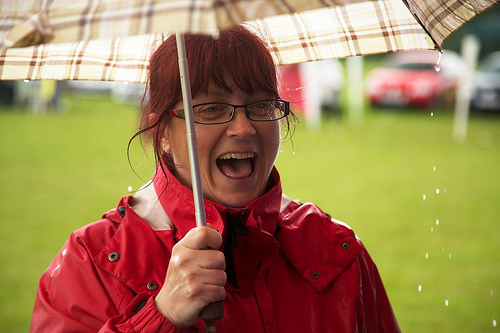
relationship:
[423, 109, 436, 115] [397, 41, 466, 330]
drop of rain water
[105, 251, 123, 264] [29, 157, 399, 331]
button on coat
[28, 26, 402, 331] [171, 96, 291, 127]
woman wearing glasses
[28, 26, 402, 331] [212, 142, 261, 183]
woman has mouth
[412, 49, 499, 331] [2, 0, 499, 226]
rain dripping from umbrella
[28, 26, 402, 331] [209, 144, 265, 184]
woman has mouth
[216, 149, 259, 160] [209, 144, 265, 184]
teeth in mouth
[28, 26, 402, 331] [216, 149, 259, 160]
woman has teeth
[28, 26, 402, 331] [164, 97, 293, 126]
woman wearing glasses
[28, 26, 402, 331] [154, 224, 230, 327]
woman has hand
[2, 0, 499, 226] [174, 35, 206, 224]
umbrella has handle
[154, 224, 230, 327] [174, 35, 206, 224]
hand holding handle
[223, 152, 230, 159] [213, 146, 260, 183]
teeth in mouth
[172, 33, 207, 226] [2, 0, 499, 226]
handle on umbrella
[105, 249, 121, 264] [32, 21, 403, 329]
snap on jacket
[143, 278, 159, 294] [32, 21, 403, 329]
snap on jacket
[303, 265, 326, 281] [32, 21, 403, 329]
snap on jacket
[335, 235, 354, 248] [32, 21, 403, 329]
snap on jacket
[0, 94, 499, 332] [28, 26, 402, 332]
grass behind woman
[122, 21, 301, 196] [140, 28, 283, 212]
hair on head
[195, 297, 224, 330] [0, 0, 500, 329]
handle on umbrella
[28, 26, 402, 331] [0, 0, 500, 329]
woman standing under umbrella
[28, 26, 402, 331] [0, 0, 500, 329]
woman holding umbrella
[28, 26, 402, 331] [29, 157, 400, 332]
woman wearing coat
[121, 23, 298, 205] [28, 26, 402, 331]
hair on woman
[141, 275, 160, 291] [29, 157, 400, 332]
button on coat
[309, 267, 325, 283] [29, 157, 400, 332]
button on coat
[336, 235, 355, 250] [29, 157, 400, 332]
button on coat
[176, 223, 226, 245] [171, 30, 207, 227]
finger wrapped around rod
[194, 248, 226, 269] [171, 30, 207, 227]
finger wrapped around rod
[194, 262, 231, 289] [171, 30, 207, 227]
finger wrapped around rod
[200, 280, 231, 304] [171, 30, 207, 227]
finger wrapped around rod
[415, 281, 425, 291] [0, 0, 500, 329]
water falling from umbrella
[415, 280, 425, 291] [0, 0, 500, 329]
water falling from umbrella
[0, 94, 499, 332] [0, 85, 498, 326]
grass on ground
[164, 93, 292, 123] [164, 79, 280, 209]
glass rims on face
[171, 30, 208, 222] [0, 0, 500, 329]
rod on umbrella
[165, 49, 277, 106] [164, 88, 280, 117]
bangs on forehead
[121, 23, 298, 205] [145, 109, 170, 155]
hair over ear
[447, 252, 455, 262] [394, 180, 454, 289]
rain drop  falling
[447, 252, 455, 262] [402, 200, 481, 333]
rain drop  falling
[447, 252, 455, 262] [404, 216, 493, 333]
rain drop  falling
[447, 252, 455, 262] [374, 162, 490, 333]
rain drop  falling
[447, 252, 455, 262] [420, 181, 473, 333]
rain drop  falling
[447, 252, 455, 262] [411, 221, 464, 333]
rain drop  falling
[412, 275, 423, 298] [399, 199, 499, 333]
rain drop  falling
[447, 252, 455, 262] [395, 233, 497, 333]
rain drop  falling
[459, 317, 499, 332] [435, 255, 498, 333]
drop of water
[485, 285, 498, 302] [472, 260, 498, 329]
drop of water